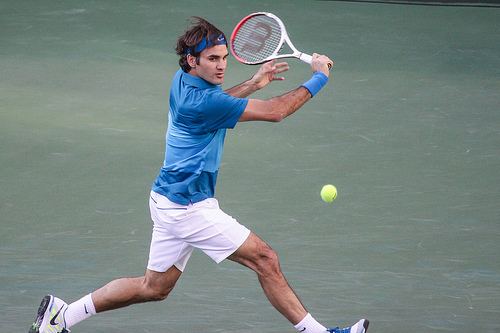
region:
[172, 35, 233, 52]
A blue head band.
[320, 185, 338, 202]
A yellow tennis ball.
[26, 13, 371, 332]
A male tennis player.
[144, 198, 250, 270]
The tennis players white shorts.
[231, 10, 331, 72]
The white and red rimmed tennis racket.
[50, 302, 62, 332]
The Nike emblem on his sneakers.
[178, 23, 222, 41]
His dark brown hair.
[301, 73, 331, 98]
A blue wrist band.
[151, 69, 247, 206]
The man's blue shirt.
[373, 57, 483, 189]
The floor of the court.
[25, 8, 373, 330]
tennis player is very goodlooking.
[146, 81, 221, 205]
tennis player's shirt is all wrinkly on the back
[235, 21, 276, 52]
tennis racket is held sideways so its wilson's 'w' logo looks like a 3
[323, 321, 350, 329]
tennis player has bright blue shoelaces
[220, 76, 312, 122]
tennis player has very furry forearms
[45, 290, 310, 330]
tennis player has nike logos not only on tennis shoes but on tennis socks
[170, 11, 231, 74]
tennis player has dark brown hair whipping around in the air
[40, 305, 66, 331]
tennis shoes have glow in the dark green stripes upon them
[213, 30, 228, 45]
tennis headband has little white nike logo on it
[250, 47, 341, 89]
tennis player's hands are lighter skinned than most of the rest of tennis player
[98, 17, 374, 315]
The man is playing tennis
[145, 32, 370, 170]
The straps trap sweat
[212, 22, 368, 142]
He is holding a tennis racket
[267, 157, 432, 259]
The ball is lime green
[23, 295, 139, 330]
His shoes and socks are Nike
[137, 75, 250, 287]
He is wearing blue and white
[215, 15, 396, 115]
His racket is white and red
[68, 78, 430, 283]
The court is green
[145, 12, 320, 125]
The man has brown hair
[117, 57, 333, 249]
His shirt has 3 stripes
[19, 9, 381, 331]
A man playing tennis.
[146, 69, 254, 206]
Man wearing blue tennis shirt.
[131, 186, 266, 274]
Man wearing white tennis shorts.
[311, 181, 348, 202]
A yellow tennis ball.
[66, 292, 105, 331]
A man's white sock.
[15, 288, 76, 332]
A man's white and blue tennis shoe.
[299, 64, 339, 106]
Blue band around man's wrist.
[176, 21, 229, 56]
Blue band around man's head.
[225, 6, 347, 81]
Man holding white and red tennis racket.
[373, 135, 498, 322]
A green tennis court.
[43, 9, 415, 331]
man swinging at tennis ball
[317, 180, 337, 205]
yellow tennis ball midair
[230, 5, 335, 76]
red and white tennis racket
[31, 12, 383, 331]
man wearing blue shirt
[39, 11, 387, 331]
man wearing white shorts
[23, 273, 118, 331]
white Nike tennis shoes and socks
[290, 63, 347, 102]
blue wristband on right arm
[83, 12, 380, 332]
man wearing blue sweatband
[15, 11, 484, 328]
Dark green tennis court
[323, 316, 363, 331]
bright blue tennis shoe laces